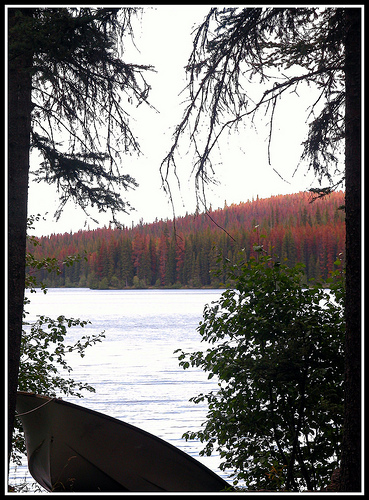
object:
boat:
[12, 388, 244, 494]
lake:
[18, 286, 354, 492]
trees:
[8, 3, 161, 466]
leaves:
[60, 25, 67, 33]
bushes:
[171, 236, 345, 492]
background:
[7, 8, 361, 495]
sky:
[26, 5, 345, 241]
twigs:
[255, 82, 293, 110]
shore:
[11, 479, 363, 492]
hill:
[25, 187, 345, 287]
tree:
[158, 8, 359, 497]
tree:
[24, 189, 345, 290]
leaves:
[158, 243, 161, 247]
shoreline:
[25, 286, 340, 291]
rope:
[14, 395, 53, 421]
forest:
[25, 188, 346, 289]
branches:
[265, 97, 276, 168]